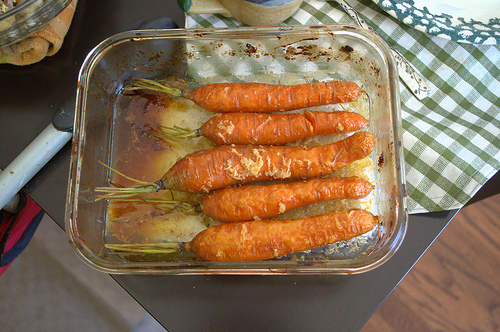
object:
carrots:
[92, 77, 379, 263]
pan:
[64, 24, 409, 278]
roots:
[98, 79, 204, 264]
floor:
[0, 0, 500, 331]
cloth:
[185, 0, 499, 212]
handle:
[2, 92, 71, 217]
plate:
[373, 0, 499, 47]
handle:
[333, 0, 429, 105]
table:
[2, 0, 500, 331]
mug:
[184, 0, 316, 34]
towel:
[0, 0, 77, 67]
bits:
[152, 35, 380, 83]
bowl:
[0, 0, 79, 52]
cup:
[180, 0, 309, 27]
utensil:
[331, 0, 435, 103]